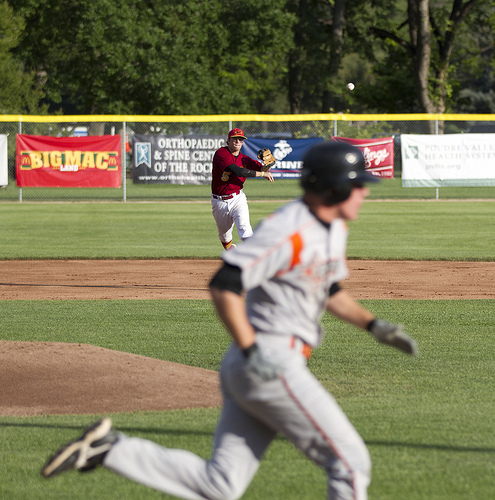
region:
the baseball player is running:
[21, 126, 429, 491]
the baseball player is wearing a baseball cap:
[294, 137, 385, 194]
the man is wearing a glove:
[362, 308, 424, 361]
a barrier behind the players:
[1, 112, 493, 205]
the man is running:
[197, 122, 278, 242]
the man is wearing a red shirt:
[206, 144, 263, 201]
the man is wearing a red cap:
[224, 120, 250, 137]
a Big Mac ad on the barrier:
[13, 129, 126, 191]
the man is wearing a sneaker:
[32, 414, 116, 481]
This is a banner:
[5, 126, 125, 199]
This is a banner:
[125, 128, 236, 197]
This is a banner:
[235, 129, 325, 188]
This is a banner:
[323, 127, 402, 199]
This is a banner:
[394, 127, 492, 199]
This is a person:
[204, 110, 261, 252]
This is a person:
[27, 143, 427, 488]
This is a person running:
[205, 119, 272, 252]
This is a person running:
[47, 142, 434, 497]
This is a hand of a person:
[311, 249, 443, 370]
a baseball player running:
[42, 139, 418, 496]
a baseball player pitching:
[207, 127, 277, 254]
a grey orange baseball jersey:
[224, 196, 349, 340]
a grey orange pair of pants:
[100, 338, 371, 499]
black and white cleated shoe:
[37, 415, 118, 480]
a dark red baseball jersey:
[206, 144, 261, 195]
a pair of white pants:
[207, 190, 253, 238]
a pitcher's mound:
[2, 340, 241, 412]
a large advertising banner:
[14, 133, 123, 188]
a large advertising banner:
[130, 135, 224, 184]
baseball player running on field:
[41, 141, 420, 498]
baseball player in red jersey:
[207, 125, 275, 252]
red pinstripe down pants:
[277, 364, 361, 499]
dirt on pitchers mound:
[1, 323, 227, 419]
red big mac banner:
[14, 132, 123, 190]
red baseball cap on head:
[224, 122, 250, 150]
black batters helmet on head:
[297, 134, 384, 228]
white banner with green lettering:
[398, 130, 494, 192]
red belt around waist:
[207, 184, 243, 203]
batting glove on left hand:
[357, 308, 427, 359]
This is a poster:
[12, 127, 129, 197]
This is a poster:
[126, 127, 242, 192]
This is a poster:
[235, 128, 329, 194]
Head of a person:
[291, 129, 384, 231]